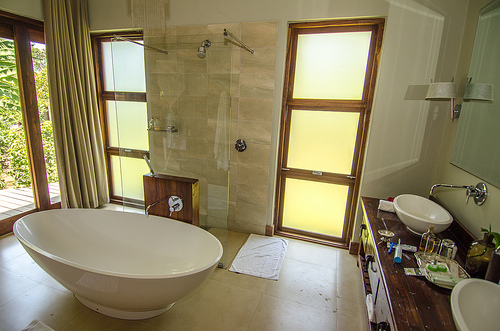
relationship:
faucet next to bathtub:
[144, 194, 166, 218] [12, 207, 223, 323]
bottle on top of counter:
[417, 222, 437, 253] [357, 193, 479, 329]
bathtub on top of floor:
[12, 207, 223, 323] [0, 199, 370, 330]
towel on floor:
[228, 229, 290, 283] [0, 199, 370, 330]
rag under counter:
[365, 292, 375, 322] [357, 193, 479, 329]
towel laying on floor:
[228, 229, 290, 283] [0, 199, 370, 330]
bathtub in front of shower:
[12, 207, 223, 323] [116, 23, 285, 243]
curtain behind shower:
[42, 0, 112, 209] [116, 23, 285, 243]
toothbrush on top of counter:
[392, 237, 404, 262] [357, 193, 479, 329]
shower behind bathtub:
[116, 23, 285, 243] [12, 207, 223, 323]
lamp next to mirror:
[425, 78, 460, 119] [448, 0, 498, 188]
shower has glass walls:
[116, 23, 285, 243] [105, 32, 231, 265]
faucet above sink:
[428, 181, 486, 205] [391, 193, 453, 238]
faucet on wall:
[428, 181, 486, 205] [435, 4, 499, 252]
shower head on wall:
[195, 36, 212, 62] [75, 0, 385, 253]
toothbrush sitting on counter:
[392, 237, 404, 262] [358, 195, 462, 329]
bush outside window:
[0, 38, 57, 191] [0, 24, 38, 213]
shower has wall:
[116, 23, 285, 243] [141, 20, 280, 233]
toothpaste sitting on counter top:
[385, 242, 416, 253] [359, 193, 479, 329]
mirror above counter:
[448, 0, 498, 188] [357, 193, 479, 329]